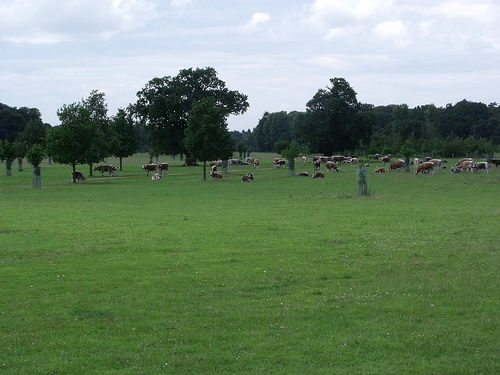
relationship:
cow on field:
[140, 162, 158, 178] [2, 151, 500, 373]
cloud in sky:
[244, 10, 280, 41] [1, 0, 499, 135]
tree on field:
[183, 97, 237, 181] [2, 151, 500, 373]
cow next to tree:
[93, 164, 119, 177] [104, 108, 143, 172]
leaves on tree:
[108, 109, 140, 159] [104, 108, 143, 172]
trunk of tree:
[118, 157, 123, 172] [104, 108, 143, 172]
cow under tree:
[93, 164, 119, 177] [104, 108, 143, 172]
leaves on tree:
[183, 95, 236, 163] [183, 97, 237, 181]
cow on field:
[207, 169, 227, 179] [2, 151, 500, 373]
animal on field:
[309, 169, 326, 178] [2, 151, 500, 373]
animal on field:
[324, 163, 343, 172] [2, 151, 500, 373]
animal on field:
[239, 170, 256, 184] [2, 151, 500, 373]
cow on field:
[70, 170, 90, 183] [2, 151, 500, 373]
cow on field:
[389, 159, 406, 172] [2, 151, 500, 373]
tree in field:
[183, 97, 237, 181] [2, 151, 500, 373]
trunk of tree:
[203, 158, 208, 183] [183, 97, 237, 181]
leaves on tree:
[46, 120, 107, 163] [46, 115, 120, 181]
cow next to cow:
[93, 164, 119, 177] [70, 170, 90, 183]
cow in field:
[140, 162, 158, 178] [2, 151, 500, 373]